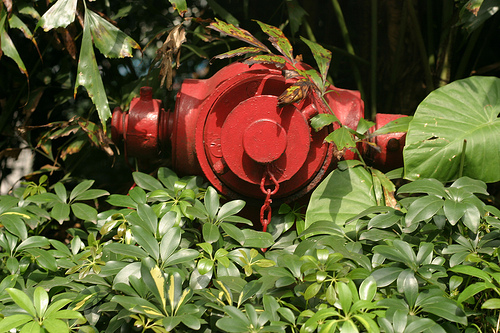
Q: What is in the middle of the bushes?
A: Fire hydrant.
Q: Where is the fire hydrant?
A: Middle of the bushes.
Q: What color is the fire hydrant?
A: Red.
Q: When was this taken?
A: Daytime.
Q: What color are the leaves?
A: Green.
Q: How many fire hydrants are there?
A: 1.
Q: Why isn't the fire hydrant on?
A: No fire.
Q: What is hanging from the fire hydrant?
A: Chain.